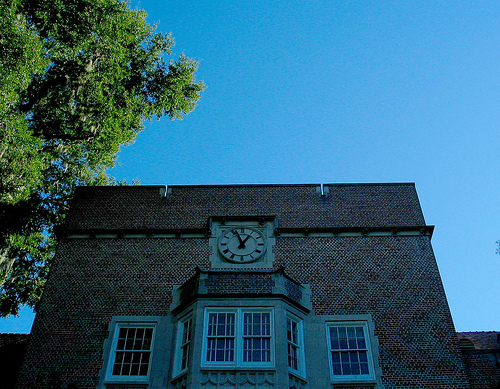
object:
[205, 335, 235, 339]
rods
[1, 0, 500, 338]
blue sky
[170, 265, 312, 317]
stone balcony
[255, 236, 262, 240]
numeral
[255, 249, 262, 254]
numeral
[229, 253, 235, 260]
numeral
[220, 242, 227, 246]
numeral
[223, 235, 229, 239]
numeral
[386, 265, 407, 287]
stone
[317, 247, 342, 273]
stone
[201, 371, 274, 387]
stone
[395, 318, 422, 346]
stone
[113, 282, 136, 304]
stone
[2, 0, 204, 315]
tree top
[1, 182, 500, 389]
building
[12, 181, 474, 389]
wall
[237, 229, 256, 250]
hand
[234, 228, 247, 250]
hands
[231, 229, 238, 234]
black metal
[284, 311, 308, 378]
windows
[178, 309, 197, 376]
windows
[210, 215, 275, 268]
clock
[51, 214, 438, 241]
wood guttering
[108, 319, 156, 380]
window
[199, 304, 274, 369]
window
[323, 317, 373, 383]
window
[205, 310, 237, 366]
window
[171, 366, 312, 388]
ledge